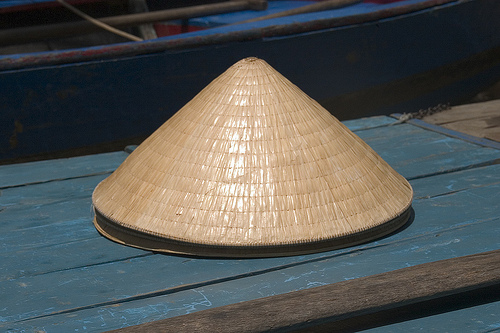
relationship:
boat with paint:
[4, 2, 497, 160] [0, 1, 497, 157]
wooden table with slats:
[2, 112, 498, 330] [2, 121, 499, 331]